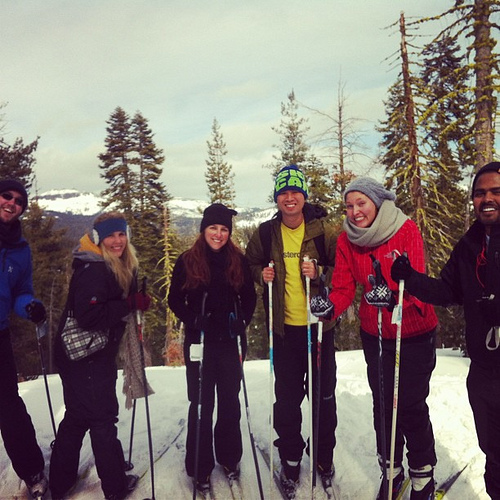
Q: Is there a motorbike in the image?
A: No, there are no motorcycles.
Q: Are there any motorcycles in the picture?
A: No, there are no motorcycles.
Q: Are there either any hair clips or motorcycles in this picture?
A: No, there are no motorcycles or hair clips.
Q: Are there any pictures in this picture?
A: No, there are no pictures.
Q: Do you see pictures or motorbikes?
A: No, there are no pictures or motorbikes.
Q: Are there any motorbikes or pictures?
A: No, there are no pictures or motorbikes.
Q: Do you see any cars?
A: No, there are no cars.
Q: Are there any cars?
A: No, there are no cars.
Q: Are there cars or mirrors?
A: No, there are no cars or mirrors.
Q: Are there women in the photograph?
A: Yes, there is a woman.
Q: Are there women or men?
A: Yes, there is a woman.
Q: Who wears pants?
A: The woman wears pants.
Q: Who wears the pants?
A: The woman wears pants.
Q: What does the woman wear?
A: The woman wears trousers.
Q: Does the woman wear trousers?
A: Yes, the woman wears trousers.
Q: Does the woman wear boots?
A: No, the woman wears trousers.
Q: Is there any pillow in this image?
A: No, there are no pillows.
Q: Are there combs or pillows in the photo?
A: No, there are no pillows or combs.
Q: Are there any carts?
A: No, there are no carts.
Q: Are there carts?
A: No, there are no carts.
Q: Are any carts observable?
A: No, there are no carts.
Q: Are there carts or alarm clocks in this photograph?
A: No, there are no carts or alarm clocks.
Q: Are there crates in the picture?
A: No, there are no crates.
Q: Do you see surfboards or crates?
A: No, there are no crates or surfboards.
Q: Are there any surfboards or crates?
A: No, there are no crates or surfboards.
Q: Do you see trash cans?
A: No, there are no trash cans.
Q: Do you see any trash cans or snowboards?
A: No, there are no trash cans or snowboards.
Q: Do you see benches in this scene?
A: No, there are no benches.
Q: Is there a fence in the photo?
A: No, there are no fences.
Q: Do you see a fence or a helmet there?
A: No, there are no fences or helmets.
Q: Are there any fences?
A: No, there are no fences.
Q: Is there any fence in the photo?
A: No, there are no fences.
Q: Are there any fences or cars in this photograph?
A: No, there are no fences or cars.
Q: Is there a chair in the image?
A: No, there are no chairs.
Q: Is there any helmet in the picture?
A: No, there are no helmets.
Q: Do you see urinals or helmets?
A: No, there are no helmets or urinals.